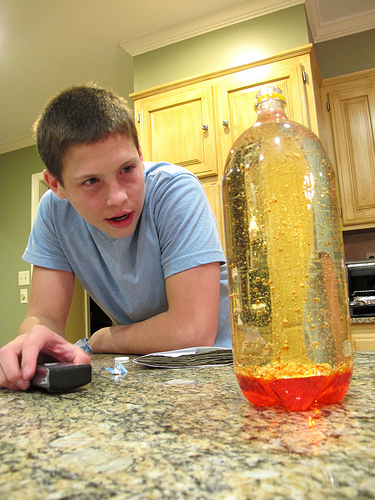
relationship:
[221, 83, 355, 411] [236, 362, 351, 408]
bottle with liquid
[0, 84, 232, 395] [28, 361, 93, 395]
boy holding object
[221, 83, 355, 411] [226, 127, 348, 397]
bottle with liquid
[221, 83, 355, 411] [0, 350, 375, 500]
bottle on surface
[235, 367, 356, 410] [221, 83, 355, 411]
red liquid on bottle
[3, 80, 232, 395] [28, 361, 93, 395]
boy holds object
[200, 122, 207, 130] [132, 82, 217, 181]
knobs on door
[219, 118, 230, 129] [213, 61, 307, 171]
knobs on door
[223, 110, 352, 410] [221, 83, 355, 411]
liquid in bottle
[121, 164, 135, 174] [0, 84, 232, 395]
eye of boy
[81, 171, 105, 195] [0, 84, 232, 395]
eye of boy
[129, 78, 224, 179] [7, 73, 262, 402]
door behind kid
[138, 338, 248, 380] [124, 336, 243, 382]
money in envelope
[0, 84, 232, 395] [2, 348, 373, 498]
boy leaning against counter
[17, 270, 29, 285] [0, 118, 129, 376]
light switch on wall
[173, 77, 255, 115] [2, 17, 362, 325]
cabinets on wall